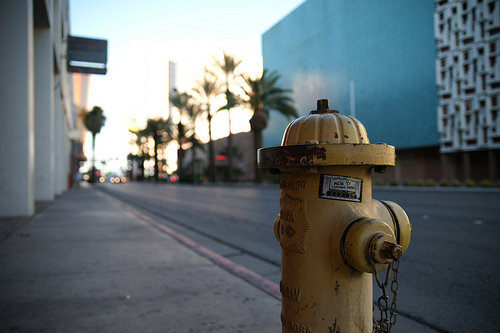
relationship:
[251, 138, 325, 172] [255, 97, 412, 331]
rust on top of hydrant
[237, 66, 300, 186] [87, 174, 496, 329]
palmtree along road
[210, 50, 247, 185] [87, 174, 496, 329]
palmtree along road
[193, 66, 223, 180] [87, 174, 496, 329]
palmtree along road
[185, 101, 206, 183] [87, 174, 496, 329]
palmtree along road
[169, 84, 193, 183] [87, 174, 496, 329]
palmtree along road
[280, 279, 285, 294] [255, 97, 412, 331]
letter on top of hydrant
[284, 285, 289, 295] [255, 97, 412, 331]
letter on top of hydrant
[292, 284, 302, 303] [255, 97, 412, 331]
letter on top of hydrant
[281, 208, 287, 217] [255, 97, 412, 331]
letter on top of hydrant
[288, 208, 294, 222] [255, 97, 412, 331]
letter on top of hydrant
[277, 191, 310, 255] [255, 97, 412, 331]
logo on top of hydrant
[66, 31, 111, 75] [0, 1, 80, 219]
sign on top of building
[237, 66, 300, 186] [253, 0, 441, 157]
tree in front of building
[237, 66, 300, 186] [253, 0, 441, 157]
palmtree in front of wall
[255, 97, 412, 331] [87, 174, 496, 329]
hydrant on top of road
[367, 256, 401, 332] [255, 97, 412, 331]
chain on top of hydrant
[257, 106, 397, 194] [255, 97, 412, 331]
paint on top of hydrant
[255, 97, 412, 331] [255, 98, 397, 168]
hydrant has cap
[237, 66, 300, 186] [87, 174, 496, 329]
palmtree on top of road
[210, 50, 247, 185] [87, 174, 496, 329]
palmtree on top of road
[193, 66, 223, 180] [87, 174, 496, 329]
palmtree on top of road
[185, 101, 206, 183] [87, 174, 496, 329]
palmtree on top of road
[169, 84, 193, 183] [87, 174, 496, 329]
palmtree on top of road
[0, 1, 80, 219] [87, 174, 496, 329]
business on top of road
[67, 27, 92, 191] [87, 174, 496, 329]
business on top of road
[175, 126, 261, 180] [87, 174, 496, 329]
business on top of road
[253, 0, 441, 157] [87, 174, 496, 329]
business on top of road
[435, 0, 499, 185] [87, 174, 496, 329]
business on top of road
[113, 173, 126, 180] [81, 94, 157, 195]
car in distance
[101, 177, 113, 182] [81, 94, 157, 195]
car in distance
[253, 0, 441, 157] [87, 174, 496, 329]
wall next to road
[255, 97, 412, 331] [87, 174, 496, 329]
hydrant near road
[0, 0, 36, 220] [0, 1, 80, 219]
pillar hanging on building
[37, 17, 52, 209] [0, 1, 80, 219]
pillar hanging on building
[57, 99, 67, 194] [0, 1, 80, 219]
pillar hanging on building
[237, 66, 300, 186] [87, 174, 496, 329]
palmtree by road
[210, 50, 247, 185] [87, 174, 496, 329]
palmtree by road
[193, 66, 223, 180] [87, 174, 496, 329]
palmtree by road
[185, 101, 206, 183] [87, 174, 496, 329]
palmtree by road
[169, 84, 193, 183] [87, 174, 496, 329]
palmtree by road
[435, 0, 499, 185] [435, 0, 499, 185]
business on top of business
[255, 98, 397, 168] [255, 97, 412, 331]
cap on top of hydrant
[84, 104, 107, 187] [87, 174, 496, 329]
palmtree left of road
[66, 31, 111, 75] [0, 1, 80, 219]
sign hanging on building